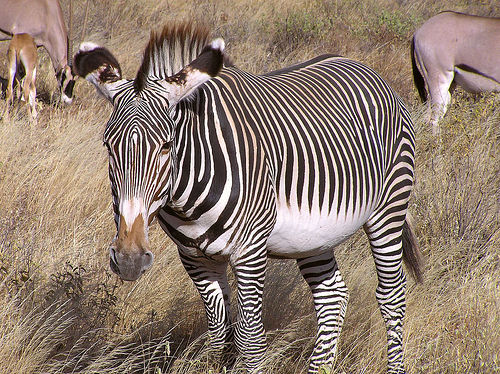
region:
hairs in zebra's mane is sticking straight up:
[112, 23, 249, 93]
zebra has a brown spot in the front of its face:
[110, 203, 158, 283]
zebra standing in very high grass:
[5, 28, 491, 359]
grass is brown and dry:
[22, 11, 472, 361]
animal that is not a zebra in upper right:
[410, 0, 498, 132]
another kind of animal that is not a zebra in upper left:
[5, 5, 75, 116]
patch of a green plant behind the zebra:
[263, 12, 418, 47]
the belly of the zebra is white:
[265, 210, 380, 255]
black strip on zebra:
[369, 235, 400, 250]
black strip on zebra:
[374, 253, 401, 265]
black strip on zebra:
[367, 223, 402, 244]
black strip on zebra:
[368, 213, 405, 235]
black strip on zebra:
[381, 176, 413, 207]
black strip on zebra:
[298, 256, 333, 270]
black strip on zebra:
[301, 263, 335, 280]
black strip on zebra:
[322, 307, 344, 313]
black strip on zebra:
[191, 271, 209, 283]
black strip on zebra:
[237, 268, 266, 276]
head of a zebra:
[39, 30, 247, 273]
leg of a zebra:
[179, 252, 236, 364]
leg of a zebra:
[218, 253, 306, 372]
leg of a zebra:
[263, 253, 368, 372]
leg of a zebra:
[353, 230, 427, 365]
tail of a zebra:
[386, 205, 451, 290]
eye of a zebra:
[94, 134, 133, 176]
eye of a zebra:
[142, 120, 196, 172]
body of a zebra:
[180, 39, 435, 274]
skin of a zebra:
[229, 62, 420, 209]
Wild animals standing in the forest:
[6, 3, 499, 367]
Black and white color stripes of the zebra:
[267, 90, 417, 202]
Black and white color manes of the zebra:
[131, 17, 225, 61]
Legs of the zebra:
[183, 290, 418, 362]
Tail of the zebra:
[405, 215, 435, 287]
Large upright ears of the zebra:
[60, 35, 242, 88]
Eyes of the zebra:
[98, 133, 182, 158]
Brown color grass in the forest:
[8, 160, 82, 307]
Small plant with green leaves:
[263, 10, 411, 42]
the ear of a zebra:
[158, 33, 232, 108]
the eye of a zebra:
[159, 132, 176, 156]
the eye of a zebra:
[96, 131, 116, 158]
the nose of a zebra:
[107, 245, 159, 272]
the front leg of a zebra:
[230, 184, 275, 372]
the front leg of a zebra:
[185, 239, 232, 373]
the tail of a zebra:
[396, 207, 437, 296]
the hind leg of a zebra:
[367, 181, 414, 372]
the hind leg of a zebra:
[301, 239, 356, 372]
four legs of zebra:
[178, 199, 433, 368]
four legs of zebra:
[167, 234, 428, 360]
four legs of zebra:
[204, 245, 427, 367]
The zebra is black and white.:
[78, 52, 443, 349]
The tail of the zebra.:
[395, 198, 434, 281]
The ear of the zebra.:
[147, 48, 227, 99]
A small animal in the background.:
[6, 34, 51, 116]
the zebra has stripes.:
[194, 82, 396, 199]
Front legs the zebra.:
[188, 264, 255, 371]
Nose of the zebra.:
[96, 235, 147, 280]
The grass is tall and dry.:
[12, 143, 170, 355]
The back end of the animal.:
[388, 15, 465, 92]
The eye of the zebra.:
[142, 130, 181, 160]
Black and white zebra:
[72, 43, 424, 373]